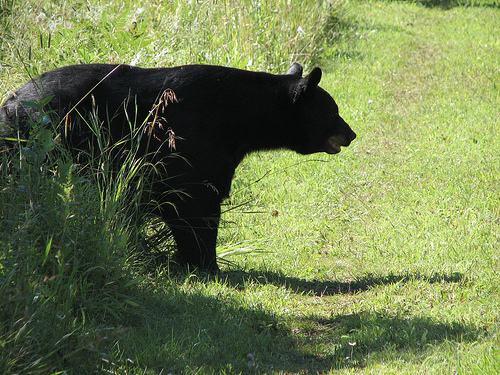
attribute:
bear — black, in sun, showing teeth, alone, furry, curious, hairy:
[1, 61, 358, 271]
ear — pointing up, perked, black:
[286, 62, 303, 76]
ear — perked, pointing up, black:
[304, 68, 323, 88]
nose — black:
[351, 131, 356, 140]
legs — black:
[152, 206, 221, 273]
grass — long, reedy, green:
[74, 106, 97, 137]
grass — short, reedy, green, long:
[230, 159, 331, 199]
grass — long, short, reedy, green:
[220, 198, 254, 212]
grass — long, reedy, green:
[132, 95, 139, 127]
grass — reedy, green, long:
[1, 135, 29, 143]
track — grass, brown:
[320, 14, 440, 316]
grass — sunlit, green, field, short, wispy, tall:
[0, 0, 498, 374]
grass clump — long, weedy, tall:
[1, 58, 232, 324]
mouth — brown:
[328, 133, 349, 151]